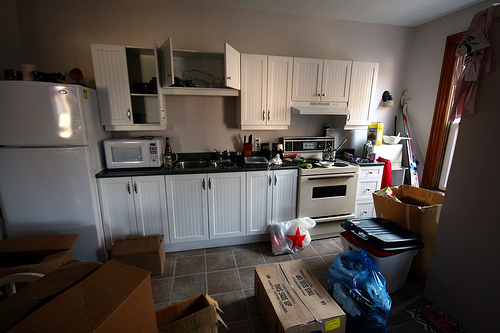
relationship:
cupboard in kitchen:
[88, 39, 168, 140] [4, 3, 493, 324]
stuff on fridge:
[0, 62, 98, 90] [2, 78, 108, 266]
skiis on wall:
[391, 84, 429, 214] [378, 25, 436, 177]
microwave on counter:
[102, 136, 166, 172] [95, 151, 390, 176]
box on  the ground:
[251, 256, 348, 331] [148, 236, 481, 332]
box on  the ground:
[112, 225, 166, 277] [148, 236, 481, 332]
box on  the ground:
[158, 293, 224, 331] [148, 236, 481, 332]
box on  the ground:
[7, 257, 161, 332] [148, 236, 481, 332]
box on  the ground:
[1, 227, 78, 277] [148, 236, 481, 332]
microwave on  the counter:
[102, 139, 165, 171] [94, 160, 302, 182]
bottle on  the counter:
[158, 134, 180, 171] [91, 144, 272, 176]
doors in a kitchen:
[167, 169, 306, 241] [20, 21, 485, 318]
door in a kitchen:
[267, 54, 292, 124] [20, 21, 485, 318]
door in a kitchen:
[241, 53, 268, 127] [20, 21, 485, 318]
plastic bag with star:
[265, 213, 320, 258] [289, 226, 307, 256]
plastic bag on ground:
[265, 213, 320, 258] [253, 251, 326, 265]